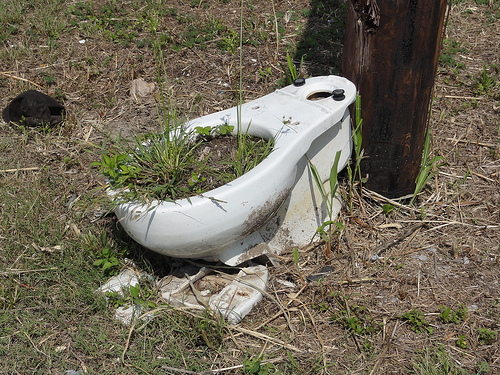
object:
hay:
[361, 188, 499, 231]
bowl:
[120, 121, 278, 201]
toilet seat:
[92, 256, 270, 327]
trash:
[0, 0, 499, 374]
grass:
[191, 123, 235, 140]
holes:
[249, 104, 261, 112]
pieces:
[92, 257, 269, 332]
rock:
[1, 89, 68, 138]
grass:
[0, 0, 308, 59]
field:
[0, 0, 498, 373]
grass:
[218, 0, 285, 178]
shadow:
[96, 210, 273, 283]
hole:
[304, 91, 335, 103]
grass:
[397, 307, 434, 336]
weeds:
[99, 120, 276, 200]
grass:
[406, 129, 446, 208]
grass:
[88, 149, 143, 189]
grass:
[90, 247, 121, 274]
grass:
[41, 73, 56, 89]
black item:
[0, 89, 67, 129]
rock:
[126, 78, 161, 107]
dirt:
[0, 0, 499, 374]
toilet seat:
[103, 119, 281, 214]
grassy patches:
[1, 0, 500, 374]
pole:
[335, 0, 450, 205]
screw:
[291, 78, 306, 88]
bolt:
[291, 76, 306, 87]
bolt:
[330, 89, 345, 101]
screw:
[331, 88, 346, 100]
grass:
[186, 168, 209, 186]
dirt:
[134, 134, 272, 202]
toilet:
[103, 74, 358, 267]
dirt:
[232, 188, 298, 268]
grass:
[451, 334, 469, 350]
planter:
[278, 51, 306, 88]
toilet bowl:
[116, 122, 275, 202]